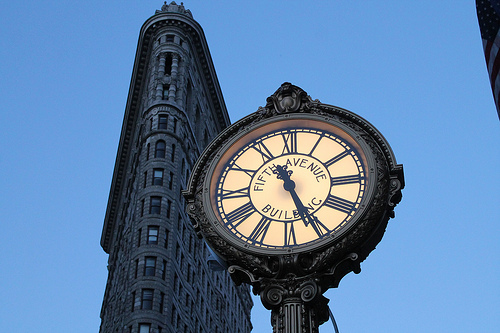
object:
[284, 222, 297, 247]
roman numeral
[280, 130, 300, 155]
roman numeral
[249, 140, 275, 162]
roman numeral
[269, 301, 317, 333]
post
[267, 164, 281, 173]
h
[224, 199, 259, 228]
numerals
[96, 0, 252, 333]
building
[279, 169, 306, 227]
hour hand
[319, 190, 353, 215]
roman numeral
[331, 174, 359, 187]
roman numeral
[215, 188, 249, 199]
roman numeral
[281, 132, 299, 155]
xii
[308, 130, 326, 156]
roman numerals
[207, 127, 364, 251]
clock